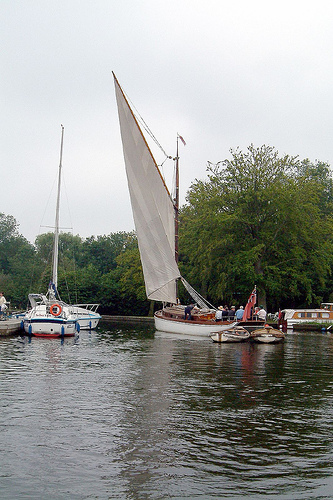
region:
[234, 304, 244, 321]
man wearing a blue shirt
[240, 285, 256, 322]
large red and blue flag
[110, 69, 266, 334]
white and brown sailboat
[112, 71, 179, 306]
large white sail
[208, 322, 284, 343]
two small wood boats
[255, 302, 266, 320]
man in a white shirt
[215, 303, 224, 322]
person wearing a hat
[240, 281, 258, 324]
flag on small boat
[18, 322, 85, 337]
blue bumpers hang on a boat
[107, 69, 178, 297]
sail being hoisted on mast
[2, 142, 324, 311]
trees all along the shore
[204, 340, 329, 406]
reflections in the ripples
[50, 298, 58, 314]
an orange life preserver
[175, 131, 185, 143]
flag high on the mast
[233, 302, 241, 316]
person wears a blue shirt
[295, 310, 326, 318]
curtains in the boat windows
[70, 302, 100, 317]
railing on the boat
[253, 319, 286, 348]
small boat in the water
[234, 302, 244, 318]
man wearing light blue shirt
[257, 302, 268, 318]
man wearing green baseball hat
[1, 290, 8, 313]
woman wearing white shirt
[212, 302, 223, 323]
man wearing a straw hat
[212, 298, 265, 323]
people sitting on a boat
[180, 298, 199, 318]
man wearing dark blue shirt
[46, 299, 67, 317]
orange life saving ring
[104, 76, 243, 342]
boat with large sail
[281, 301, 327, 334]
orange and white boat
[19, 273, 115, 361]
boats on the water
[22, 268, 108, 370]
boats on the water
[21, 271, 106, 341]
boats on the water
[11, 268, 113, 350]
boats on the water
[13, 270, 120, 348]
boats on the water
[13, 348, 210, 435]
the water is calm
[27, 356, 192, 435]
the water is calm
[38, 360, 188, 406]
the water is calm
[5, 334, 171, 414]
the water is calm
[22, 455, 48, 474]
Small ripples in the water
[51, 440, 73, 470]
Small ripples in the water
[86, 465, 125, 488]
Small ripples in the water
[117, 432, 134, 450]
Small ripples in the water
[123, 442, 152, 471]
Small ripples in the water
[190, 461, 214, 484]
Small ripples in the water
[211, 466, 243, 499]
Small ripples in the water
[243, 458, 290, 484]
Small ripples in the water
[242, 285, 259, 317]
a flag on a flag pole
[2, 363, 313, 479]
a body of water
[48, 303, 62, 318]
a orange life preserver